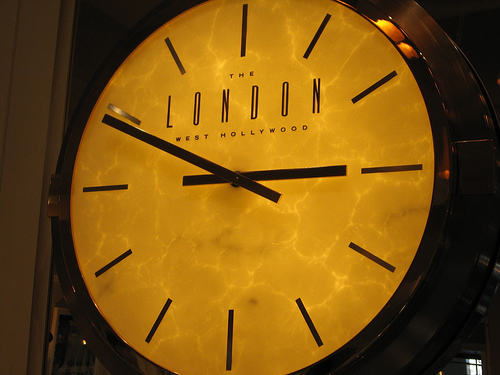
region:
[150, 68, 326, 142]
the name of the place on the clock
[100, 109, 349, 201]
the hands on the clock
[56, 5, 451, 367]
the clock hanging on the wall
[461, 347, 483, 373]
a window in the background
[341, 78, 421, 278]
some of the numbers on the clock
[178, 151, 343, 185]
the minute hand of the clock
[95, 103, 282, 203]
the hour hand of the clock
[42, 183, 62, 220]
the brass on the side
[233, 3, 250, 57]
the 12 o'clock hand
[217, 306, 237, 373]
the 6 o'clock hand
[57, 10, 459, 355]
clock on side of building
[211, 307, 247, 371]
tick mark on clock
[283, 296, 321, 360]
tick mark on clock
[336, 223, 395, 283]
tick mark on clock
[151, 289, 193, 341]
tick mark on clock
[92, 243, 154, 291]
tick mark on clock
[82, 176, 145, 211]
tick mark on clock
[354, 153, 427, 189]
tick mark on clock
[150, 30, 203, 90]
tick mark on clock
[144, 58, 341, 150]
black lettering on clock face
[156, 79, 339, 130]
london printed in black on clock face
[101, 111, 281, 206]
black minute hand of clock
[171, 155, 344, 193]
black hour hand of clock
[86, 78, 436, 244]
clock hands showing 2:49 on clock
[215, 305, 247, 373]
black dash marking 6 on clock face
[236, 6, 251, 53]
black dash marking 12 on clock face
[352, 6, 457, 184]
reflection on clock frame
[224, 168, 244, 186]
black bolt holding hands to clock face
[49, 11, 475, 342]
black frame of the clock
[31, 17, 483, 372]
The time clock is black and yellow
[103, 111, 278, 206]
Th big hand on the clock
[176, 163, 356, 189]
The small hand on the clock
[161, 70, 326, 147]
The name on the clock is "The London"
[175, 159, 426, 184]
The little hand is on the three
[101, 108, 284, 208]
The big hand in on 49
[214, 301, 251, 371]
This is the number six on the clock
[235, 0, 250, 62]
This is the number twelve on the clock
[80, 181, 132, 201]
This is the number nine on the clock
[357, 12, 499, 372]
The edge of the clock is sleek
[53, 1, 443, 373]
large clock with no numbers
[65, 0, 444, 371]
metallic clock face with black paint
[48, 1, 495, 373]
large brass clock with yellow face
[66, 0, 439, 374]
clock face with lettering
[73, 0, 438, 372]
black lines on clock face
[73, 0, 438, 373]
clock face with crackle effect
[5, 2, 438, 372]
large clock by wall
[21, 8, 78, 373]
wooden molding on wall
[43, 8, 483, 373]
large round brass clock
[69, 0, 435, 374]
round clock face with black hands